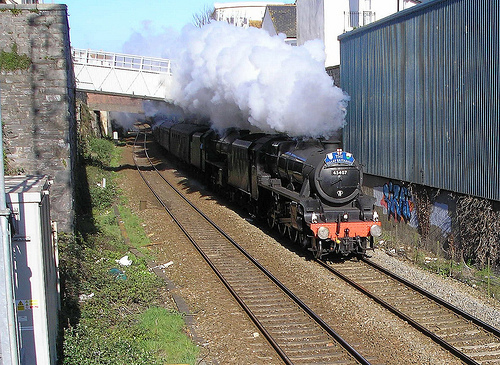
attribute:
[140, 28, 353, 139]
steam — white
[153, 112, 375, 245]
train — black, orange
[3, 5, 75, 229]
brick wall — grey, gray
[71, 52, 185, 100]
bridge — white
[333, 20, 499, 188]
metal wall — blue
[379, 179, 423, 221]
graffiti — blue, black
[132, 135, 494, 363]
train track — black copper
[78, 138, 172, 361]
grass — green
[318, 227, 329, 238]
light — white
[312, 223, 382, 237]
front of train — red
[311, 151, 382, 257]
train car — orange, blue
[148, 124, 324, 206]
train cars — black